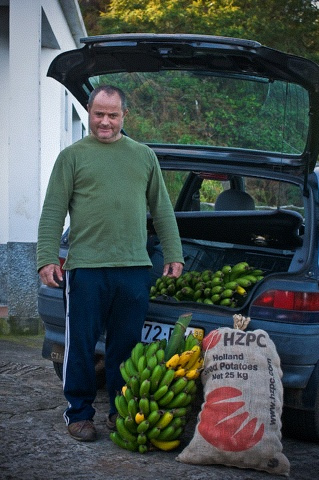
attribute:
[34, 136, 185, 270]
shirt — green, olive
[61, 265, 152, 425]
pants — navy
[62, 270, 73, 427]
stripe — white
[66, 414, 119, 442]
shoes — brown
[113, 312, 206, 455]
bananas — green, unripe, bunch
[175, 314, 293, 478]
sack — grey, burlap, tan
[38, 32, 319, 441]
car — blue, open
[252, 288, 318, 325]
tail lights — red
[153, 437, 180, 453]
banana — yellow